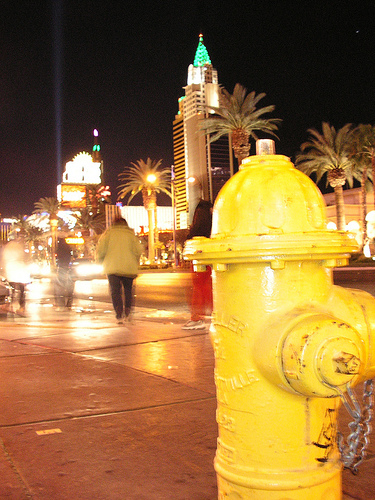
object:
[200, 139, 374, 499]
hydrant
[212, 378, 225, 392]
letters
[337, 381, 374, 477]
chain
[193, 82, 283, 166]
tree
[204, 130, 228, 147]
leaves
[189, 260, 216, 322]
pants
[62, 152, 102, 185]
sign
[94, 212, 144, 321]
person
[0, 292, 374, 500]
sidewalk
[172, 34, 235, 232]
building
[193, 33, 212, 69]
roof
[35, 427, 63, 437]
paper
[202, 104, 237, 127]
branches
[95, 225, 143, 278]
jacket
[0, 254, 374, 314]
road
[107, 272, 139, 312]
pants